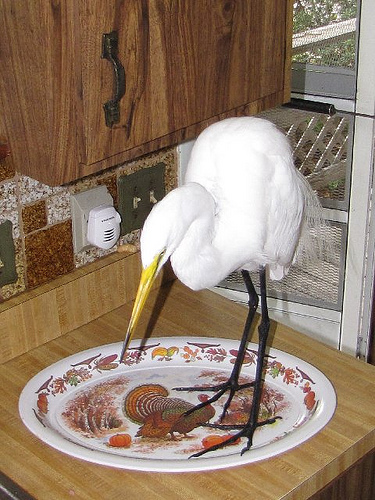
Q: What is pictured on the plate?
A: Turkey.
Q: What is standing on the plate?
A: Crane.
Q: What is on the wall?
A: Tile blacksplash.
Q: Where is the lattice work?
A: Patio.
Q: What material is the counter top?
A: Formica.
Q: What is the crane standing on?
A: Thanksgiving platter.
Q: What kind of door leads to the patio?
A: Storm door with screeen.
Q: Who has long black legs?
A: The bird.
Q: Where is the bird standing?
A: On a plate.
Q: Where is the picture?
A: On the white plate.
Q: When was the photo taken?
A: During the daytime.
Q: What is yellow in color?
A: Beak.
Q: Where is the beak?
A: On the bird.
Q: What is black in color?
A: Bird legs.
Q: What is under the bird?
A: Plate.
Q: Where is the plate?
A: On table.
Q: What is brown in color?
A: Table.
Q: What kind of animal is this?
A: A bird.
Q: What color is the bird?
A: White.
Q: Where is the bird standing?
A: On the plate.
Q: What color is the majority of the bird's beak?
A: Yellow.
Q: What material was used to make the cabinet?
A: Wood.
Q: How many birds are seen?
A: 1.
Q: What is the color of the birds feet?
A: Black.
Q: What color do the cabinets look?
A: Brown.